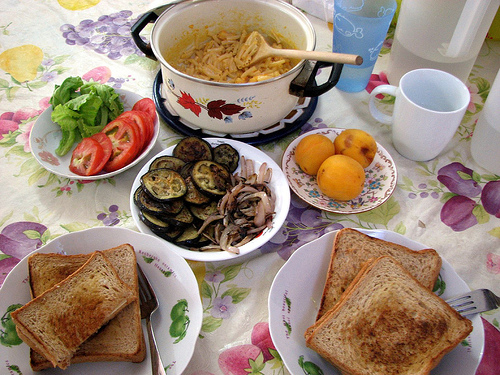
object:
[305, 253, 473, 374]
toast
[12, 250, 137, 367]
toast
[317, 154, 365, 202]
fruit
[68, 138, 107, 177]
tomato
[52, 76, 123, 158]
lettuce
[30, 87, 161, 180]
bowl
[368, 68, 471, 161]
cup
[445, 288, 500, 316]
fork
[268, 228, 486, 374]
bowl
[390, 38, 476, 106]
water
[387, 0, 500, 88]
pitcher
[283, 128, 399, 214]
plate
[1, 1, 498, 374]
table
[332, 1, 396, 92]
cup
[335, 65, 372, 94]
water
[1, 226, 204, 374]
bowl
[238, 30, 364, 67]
spoon